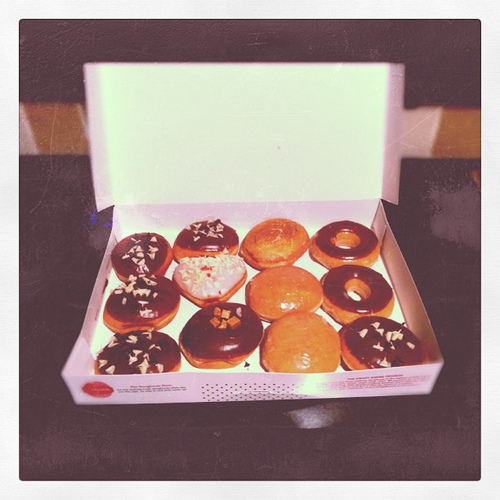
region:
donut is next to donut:
[110, 233, 170, 279]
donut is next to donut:
[172, 218, 292, 260]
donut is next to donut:
[242, 219, 307, 289]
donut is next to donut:
[310, 219, 377, 270]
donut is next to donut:
[101, 273, 181, 332]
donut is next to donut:
[172, 251, 244, 305]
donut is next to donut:
[247, 266, 323, 320]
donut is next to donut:
[319, 263, 395, 324]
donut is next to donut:
[94, 329, 183, 375]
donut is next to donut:
[179, 301, 265, 368]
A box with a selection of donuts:
[75, 206, 433, 391]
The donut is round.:
[305, 210, 383, 271]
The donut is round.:
[313, 260, 398, 326]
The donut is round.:
[332, 314, 432, 386]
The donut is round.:
[233, 216, 313, 271]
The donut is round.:
[237, 262, 324, 324]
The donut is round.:
[260, 305, 345, 383]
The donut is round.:
[169, 294, 269, 373]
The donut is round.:
[86, 323, 183, 386]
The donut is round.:
[100, 270, 184, 338]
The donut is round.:
[168, 215, 242, 266]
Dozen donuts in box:
[103, 213, 425, 386]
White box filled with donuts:
[81, 99, 446, 400]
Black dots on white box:
[197, 381, 316, 407]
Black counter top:
[15, 150, 480, 480]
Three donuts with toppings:
[114, 232, 181, 387]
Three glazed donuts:
[249, 207, 338, 384]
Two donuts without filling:
[315, 221, 390, 321]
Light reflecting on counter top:
[288, 392, 347, 436]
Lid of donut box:
[77, 58, 404, 213]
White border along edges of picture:
[4, 0, 499, 499]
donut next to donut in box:
[108, 232, 172, 279]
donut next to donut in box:
[96, 327, 182, 372]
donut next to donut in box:
[180, 301, 263, 367]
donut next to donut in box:
[259, 309, 339, 373]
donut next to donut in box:
[338, 314, 427, 369]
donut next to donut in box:
[321, 265, 394, 323]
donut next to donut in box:
[247, 265, 324, 320]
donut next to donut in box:
[173, 250, 246, 306]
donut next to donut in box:
[102, 274, 181, 333]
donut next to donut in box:
[240, 217, 312, 271]